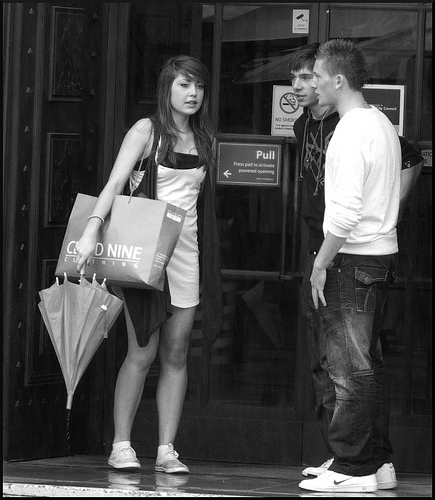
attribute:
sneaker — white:
[297, 472, 376, 492]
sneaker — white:
[376, 464, 398, 489]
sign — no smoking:
[271, 82, 305, 139]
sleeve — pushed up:
[321, 145, 366, 231]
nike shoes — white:
[296, 448, 391, 493]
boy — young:
[307, 34, 403, 489]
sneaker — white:
[295, 471, 380, 495]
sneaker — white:
[302, 457, 336, 477]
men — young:
[283, 34, 425, 495]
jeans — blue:
[299, 238, 408, 479]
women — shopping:
[65, 48, 225, 483]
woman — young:
[72, 49, 222, 483]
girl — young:
[70, 50, 214, 484]